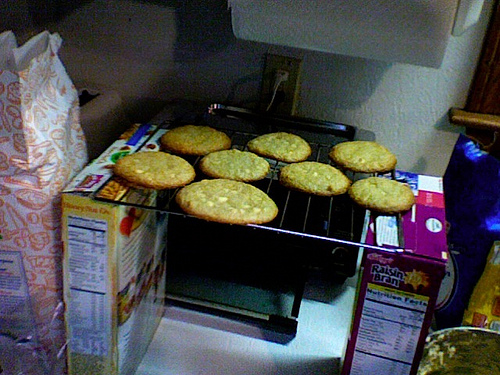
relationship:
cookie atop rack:
[178, 175, 280, 227] [92, 121, 402, 251]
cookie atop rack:
[281, 160, 352, 199] [92, 121, 402, 251]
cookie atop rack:
[330, 139, 395, 173] [92, 121, 402, 251]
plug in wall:
[260, 54, 301, 115] [0, 3, 492, 173]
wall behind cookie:
[0, 3, 492, 173] [178, 175, 280, 227]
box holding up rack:
[341, 170, 444, 373] [92, 121, 402, 251]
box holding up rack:
[62, 120, 170, 373] [92, 121, 402, 251]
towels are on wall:
[228, 0, 445, 71] [0, 3, 492, 173]